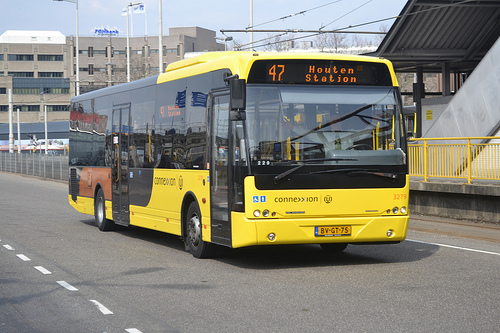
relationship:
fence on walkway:
[408, 136, 500, 185] [409, 166, 499, 186]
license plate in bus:
[307, 217, 365, 239] [47, 68, 422, 290]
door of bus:
[199, 88, 235, 230] [52, 43, 412, 255]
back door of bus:
[111, 101, 130, 227] [52, 43, 412, 255]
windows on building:
[70, 42, 157, 82] [0, 21, 239, 155]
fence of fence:
[408, 136, 500, 185] [408, 136, 499, 185]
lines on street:
[7, 245, 108, 330] [7, 176, 417, 331]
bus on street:
[52, 43, 412, 255] [4, 170, 484, 330]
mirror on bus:
[228, 77, 246, 109] [68, 51, 409, 258]